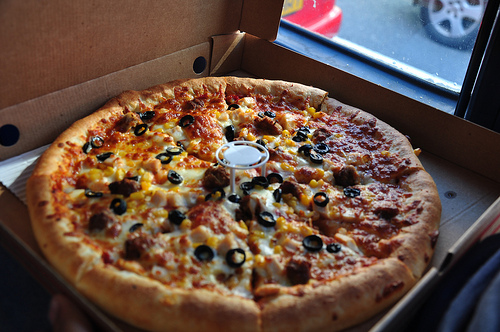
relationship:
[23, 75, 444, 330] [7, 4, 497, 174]
pizza in box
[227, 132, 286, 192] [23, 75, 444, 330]
topper for pizza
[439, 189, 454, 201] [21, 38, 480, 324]
spot on box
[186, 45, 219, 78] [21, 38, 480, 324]
hole in box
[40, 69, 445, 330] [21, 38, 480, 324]
pizza in box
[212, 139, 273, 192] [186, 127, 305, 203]
white stand in middle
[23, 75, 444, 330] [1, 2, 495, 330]
pizza in box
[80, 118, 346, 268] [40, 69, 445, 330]
olives on pizza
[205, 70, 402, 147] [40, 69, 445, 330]
crust of pizza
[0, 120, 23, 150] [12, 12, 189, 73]
hole in box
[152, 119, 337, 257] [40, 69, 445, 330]
cheese on pizza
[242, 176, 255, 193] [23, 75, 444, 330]
olive on pizza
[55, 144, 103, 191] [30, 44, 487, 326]
sauce on pizza